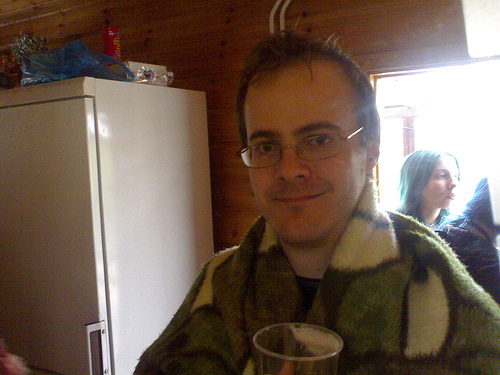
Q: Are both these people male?
A: No, they are both male and female.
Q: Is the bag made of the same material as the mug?
A: Yes, both the bag and the mug are made of plastic.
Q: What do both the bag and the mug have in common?
A: The material, both the bag and the mug are plastic.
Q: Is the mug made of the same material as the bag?
A: Yes, both the mug and the bag are made of plastic.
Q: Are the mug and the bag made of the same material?
A: Yes, both the mug and the bag are made of plastic.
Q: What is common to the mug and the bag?
A: The material, both the mug and the bag are plastic.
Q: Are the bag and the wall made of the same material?
A: No, the bag is made of plastic and the wall is made of wood.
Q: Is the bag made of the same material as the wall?
A: No, the bag is made of plastic and the wall is made of wood.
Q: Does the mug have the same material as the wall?
A: No, the mug is made of plastic and the wall is made of wood.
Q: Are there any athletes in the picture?
A: No, there are no athletes.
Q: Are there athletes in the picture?
A: No, there are no athletes.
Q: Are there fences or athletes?
A: No, there are no athletes or fences.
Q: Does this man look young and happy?
A: Yes, the man is young and happy.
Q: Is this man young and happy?
A: Yes, the man is young and happy.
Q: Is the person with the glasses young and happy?
A: Yes, the man is young and happy.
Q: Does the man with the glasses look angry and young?
A: No, the man is young but happy.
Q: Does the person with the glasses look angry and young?
A: No, the man is young but happy.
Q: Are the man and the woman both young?
A: Yes, both the man and the woman are young.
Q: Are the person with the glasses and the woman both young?
A: Yes, both the man and the woman are young.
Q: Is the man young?
A: Yes, the man is young.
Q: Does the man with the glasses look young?
A: Yes, the man is young.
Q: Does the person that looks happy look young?
A: Yes, the man is young.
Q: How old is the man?
A: The man is young.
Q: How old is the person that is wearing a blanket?
A: The man is young.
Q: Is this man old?
A: No, the man is young.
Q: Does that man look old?
A: No, the man is young.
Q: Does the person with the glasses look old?
A: No, the man is young.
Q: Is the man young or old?
A: The man is young.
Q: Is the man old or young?
A: The man is young.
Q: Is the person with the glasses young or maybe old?
A: The man is young.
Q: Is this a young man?
A: Yes, this is a young man.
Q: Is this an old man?
A: No, this is a young man.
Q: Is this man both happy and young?
A: Yes, the man is happy and young.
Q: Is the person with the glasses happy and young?
A: Yes, the man is happy and young.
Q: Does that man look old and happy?
A: No, the man is happy but young.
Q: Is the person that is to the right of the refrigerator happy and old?
A: No, the man is happy but young.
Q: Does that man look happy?
A: Yes, the man is happy.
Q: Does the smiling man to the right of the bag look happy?
A: Yes, the man is happy.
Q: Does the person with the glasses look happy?
A: Yes, the man is happy.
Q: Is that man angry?
A: No, the man is happy.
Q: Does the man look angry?
A: No, the man is happy.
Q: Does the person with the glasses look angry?
A: No, the man is happy.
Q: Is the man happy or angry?
A: The man is happy.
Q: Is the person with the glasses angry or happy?
A: The man is happy.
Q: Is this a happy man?
A: Yes, this is a happy man.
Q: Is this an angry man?
A: No, this is a happy man.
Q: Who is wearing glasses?
A: The man is wearing glasses.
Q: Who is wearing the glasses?
A: The man is wearing glasses.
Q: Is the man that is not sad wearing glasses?
A: Yes, the man is wearing glasses.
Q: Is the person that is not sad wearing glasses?
A: Yes, the man is wearing glasses.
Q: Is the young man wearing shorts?
A: No, the man is wearing glasses.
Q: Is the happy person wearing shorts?
A: No, the man is wearing glasses.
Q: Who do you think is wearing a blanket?
A: The man is wearing a blanket.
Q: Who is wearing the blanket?
A: The man is wearing a blanket.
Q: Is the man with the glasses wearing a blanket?
A: Yes, the man is wearing a blanket.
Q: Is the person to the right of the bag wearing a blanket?
A: Yes, the man is wearing a blanket.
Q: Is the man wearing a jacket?
A: No, the man is wearing a blanket.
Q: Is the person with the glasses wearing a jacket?
A: No, the man is wearing a blanket.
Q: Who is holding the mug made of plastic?
A: The man is holding the mug.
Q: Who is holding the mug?
A: The man is holding the mug.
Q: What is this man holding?
A: The man is holding the mug.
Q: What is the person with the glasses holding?
A: The man is holding the mug.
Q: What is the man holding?
A: The man is holding the mug.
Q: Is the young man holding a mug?
A: Yes, the man is holding a mug.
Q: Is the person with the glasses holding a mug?
A: Yes, the man is holding a mug.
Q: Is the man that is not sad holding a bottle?
A: No, the man is holding a mug.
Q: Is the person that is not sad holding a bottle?
A: No, the man is holding a mug.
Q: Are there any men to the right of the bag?
A: Yes, there is a man to the right of the bag.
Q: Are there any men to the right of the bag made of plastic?
A: Yes, there is a man to the right of the bag.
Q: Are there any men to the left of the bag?
A: No, the man is to the right of the bag.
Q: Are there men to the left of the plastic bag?
A: No, the man is to the right of the bag.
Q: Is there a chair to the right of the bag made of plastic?
A: No, there is a man to the right of the bag.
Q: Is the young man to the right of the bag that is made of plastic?
A: Yes, the man is to the right of the bag.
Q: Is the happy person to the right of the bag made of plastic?
A: Yes, the man is to the right of the bag.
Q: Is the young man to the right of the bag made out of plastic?
A: Yes, the man is to the right of the bag.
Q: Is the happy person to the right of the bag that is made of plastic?
A: Yes, the man is to the right of the bag.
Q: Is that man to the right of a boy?
A: No, the man is to the right of the bag.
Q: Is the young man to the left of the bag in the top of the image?
A: No, the man is to the right of the bag.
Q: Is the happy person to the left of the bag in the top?
A: No, the man is to the right of the bag.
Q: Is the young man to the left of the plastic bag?
A: No, the man is to the right of the bag.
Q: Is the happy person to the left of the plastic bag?
A: No, the man is to the right of the bag.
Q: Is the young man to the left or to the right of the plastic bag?
A: The man is to the right of the bag.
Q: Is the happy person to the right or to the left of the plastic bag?
A: The man is to the right of the bag.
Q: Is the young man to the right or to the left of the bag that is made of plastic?
A: The man is to the right of the bag.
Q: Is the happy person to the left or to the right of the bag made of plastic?
A: The man is to the right of the bag.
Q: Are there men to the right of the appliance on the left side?
A: Yes, there is a man to the right of the refrigerator.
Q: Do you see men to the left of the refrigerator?
A: No, the man is to the right of the refrigerator.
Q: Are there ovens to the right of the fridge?
A: No, there is a man to the right of the fridge.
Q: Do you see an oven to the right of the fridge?
A: No, there is a man to the right of the fridge.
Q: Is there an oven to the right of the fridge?
A: No, there is a man to the right of the fridge.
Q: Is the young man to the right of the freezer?
A: Yes, the man is to the right of the freezer.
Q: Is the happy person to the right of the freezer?
A: Yes, the man is to the right of the freezer.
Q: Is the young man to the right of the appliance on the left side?
A: Yes, the man is to the right of the freezer.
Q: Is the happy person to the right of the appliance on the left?
A: Yes, the man is to the right of the freezer.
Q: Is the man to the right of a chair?
A: No, the man is to the right of the freezer.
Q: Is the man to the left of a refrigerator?
A: No, the man is to the right of a refrigerator.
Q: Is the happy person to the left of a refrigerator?
A: No, the man is to the right of a refrigerator.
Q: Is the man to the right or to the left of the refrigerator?
A: The man is to the right of the refrigerator.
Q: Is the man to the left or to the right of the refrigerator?
A: The man is to the right of the refrigerator.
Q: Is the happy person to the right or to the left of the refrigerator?
A: The man is to the right of the refrigerator.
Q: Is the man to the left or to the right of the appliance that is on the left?
A: The man is to the right of the refrigerator.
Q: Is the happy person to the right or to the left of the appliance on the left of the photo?
A: The man is to the right of the refrigerator.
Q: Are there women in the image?
A: Yes, there is a woman.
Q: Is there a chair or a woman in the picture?
A: Yes, there is a woman.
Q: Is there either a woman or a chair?
A: Yes, there is a woman.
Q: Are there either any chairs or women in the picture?
A: Yes, there is a woman.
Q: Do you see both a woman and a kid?
A: No, there is a woman but no children.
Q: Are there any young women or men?
A: Yes, there is a young woman.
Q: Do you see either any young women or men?
A: Yes, there is a young woman.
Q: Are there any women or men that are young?
A: Yes, the woman is young.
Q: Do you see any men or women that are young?
A: Yes, the woman is young.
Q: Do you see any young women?
A: Yes, there is a young woman.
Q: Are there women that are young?
A: Yes, there is a woman that is young.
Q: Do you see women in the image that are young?
A: Yes, there is a woman that is young.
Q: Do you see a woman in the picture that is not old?
A: Yes, there is an young woman.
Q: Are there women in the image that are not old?
A: Yes, there is an young woman.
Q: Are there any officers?
A: No, there are no officers.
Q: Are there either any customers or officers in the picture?
A: No, there are no officers or customers.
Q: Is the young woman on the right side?
A: Yes, the woman is on the right of the image.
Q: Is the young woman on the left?
A: No, the woman is on the right of the image.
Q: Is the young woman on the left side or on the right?
A: The woman is on the right of the image.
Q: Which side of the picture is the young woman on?
A: The woman is on the right of the image.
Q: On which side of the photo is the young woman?
A: The woman is on the right of the image.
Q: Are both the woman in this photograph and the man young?
A: Yes, both the woman and the man are young.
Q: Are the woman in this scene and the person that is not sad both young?
A: Yes, both the woman and the man are young.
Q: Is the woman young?
A: Yes, the woman is young.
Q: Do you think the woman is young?
A: Yes, the woman is young.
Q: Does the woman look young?
A: Yes, the woman is young.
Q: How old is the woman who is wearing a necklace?
A: The woman is young.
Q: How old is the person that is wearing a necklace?
A: The woman is young.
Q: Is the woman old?
A: No, the woman is young.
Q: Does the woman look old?
A: No, the woman is young.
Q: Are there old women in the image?
A: No, there is a woman but she is young.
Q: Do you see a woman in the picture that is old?
A: No, there is a woman but she is young.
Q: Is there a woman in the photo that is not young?
A: No, there is a woman but she is young.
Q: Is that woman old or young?
A: The woman is young.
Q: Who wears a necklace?
A: The woman wears a necklace.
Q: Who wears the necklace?
A: The woman wears a necklace.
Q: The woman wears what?
A: The woman wears a necklace.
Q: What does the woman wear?
A: The woman wears a necklace.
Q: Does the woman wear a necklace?
A: Yes, the woman wears a necklace.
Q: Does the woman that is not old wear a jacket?
A: No, the woman wears a necklace.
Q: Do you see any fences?
A: No, there are no fences.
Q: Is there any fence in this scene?
A: No, there are no fences.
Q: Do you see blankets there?
A: Yes, there is a blanket.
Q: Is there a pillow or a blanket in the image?
A: Yes, there is a blanket.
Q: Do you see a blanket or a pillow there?
A: Yes, there is a blanket.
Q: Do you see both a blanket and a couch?
A: No, there is a blanket but no couches.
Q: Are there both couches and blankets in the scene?
A: No, there is a blanket but no couches.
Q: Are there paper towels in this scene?
A: No, there are no paper towels.